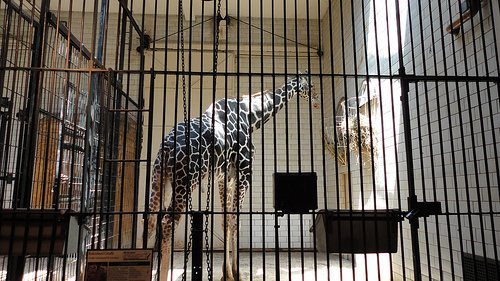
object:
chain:
[204, 2, 224, 280]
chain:
[178, 3, 193, 280]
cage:
[0, 0, 499, 280]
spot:
[218, 138, 233, 152]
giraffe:
[140, 67, 320, 280]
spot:
[152, 157, 160, 166]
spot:
[168, 146, 182, 157]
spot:
[177, 144, 193, 157]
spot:
[252, 103, 264, 119]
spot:
[238, 159, 250, 169]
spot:
[236, 146, 249, 159]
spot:
[229, 127, 248, 146]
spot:
[213, 111, 228, 123]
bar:
[235, 0, 240, 280]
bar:
[244, 0, 254, 279]